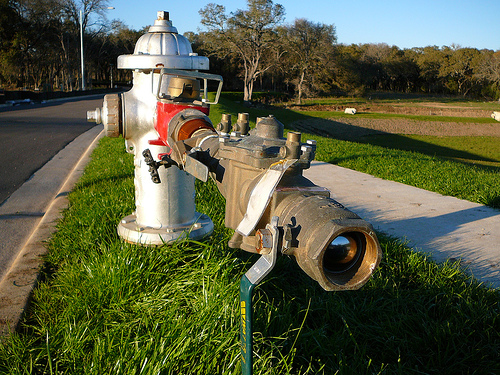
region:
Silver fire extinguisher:
[85, 8, 210, 243]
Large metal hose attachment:
[140, 110, 383, 372]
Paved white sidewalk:
[203, 125, 498, 286]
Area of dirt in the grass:
[295, 112, 497, 142]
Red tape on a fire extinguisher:
[146, 99, 211, 151]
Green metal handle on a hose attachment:
[234, 223, 279, 373]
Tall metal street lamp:
[76, 3, 116, 90]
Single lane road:
[2, 88, 127, 339]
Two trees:
[195, 0, 337, 104]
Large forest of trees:
[0, 0, 499, 110]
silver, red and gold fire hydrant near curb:
[10, 18, 381, 368]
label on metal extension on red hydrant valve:
[137, 86, 367, 317]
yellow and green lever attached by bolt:
[235, 220, 280, 370]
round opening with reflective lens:
[311, 215, 376, 290]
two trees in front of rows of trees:
[205, 5, 495, 102]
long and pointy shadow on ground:
[225, 90, 495, 180]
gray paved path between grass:
[232, 140, 494, 315]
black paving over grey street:
[0, 86, 107, 271]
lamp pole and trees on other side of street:
[1, 5, 131, 96]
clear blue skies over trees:
[62, 0, 497, 50]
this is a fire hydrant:
[81, 11, 233, 279]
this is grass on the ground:
[140, 252, 237, 367]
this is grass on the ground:
[291, 318, 338, 362]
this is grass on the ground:
[52, 281, 123, 372]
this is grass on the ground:
[384, 265, 455, 323]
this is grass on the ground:
[360, 135, 427, 190]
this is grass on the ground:
[60, 198, 130, 332]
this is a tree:
[217, 5, 309, 119]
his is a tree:
[307, 25, 375, 106]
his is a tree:
[421, 36, 489, 114]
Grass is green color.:
[75, 266, 186, 363]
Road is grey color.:
[8, 108, 66, 183]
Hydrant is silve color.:
[101, 31, 222, 257]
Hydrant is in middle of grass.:
[117, 33, 212, 278]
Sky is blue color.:
[299, 7, 499, 38]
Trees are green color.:
[13, 21, 499, 94]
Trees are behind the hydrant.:
[4, 20, 498, 122]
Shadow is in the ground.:
[200, 77, 479, 361]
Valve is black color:
[133, 145, 165, 184]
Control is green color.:
[230, 242, 277, 368]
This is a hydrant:
[73, 73, 226, 360]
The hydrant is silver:
[106, 11, 203, 183]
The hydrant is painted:
[48, 27, 186, 226]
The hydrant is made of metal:
[127, 159, 214, 286]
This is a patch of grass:
[41, 209, 207, 371]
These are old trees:
[226, 29, 312, 121]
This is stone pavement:
[14, 143, 62, 199]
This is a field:
[274, 60, 471, 152]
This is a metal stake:
[206, 230, 309, 365]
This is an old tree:
[237, 49, 276, 94]